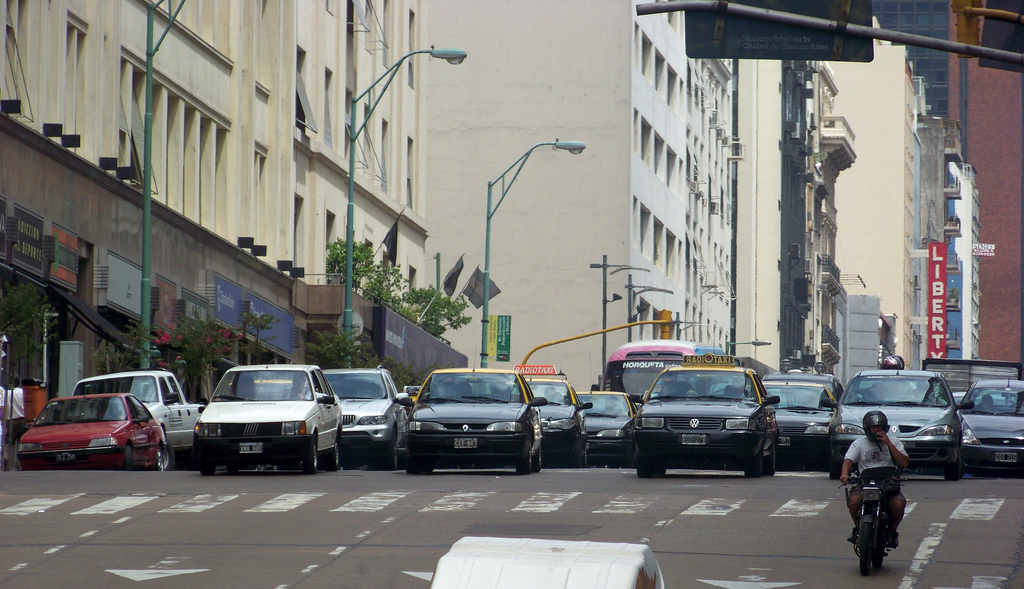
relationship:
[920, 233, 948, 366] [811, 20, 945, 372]
liberty on building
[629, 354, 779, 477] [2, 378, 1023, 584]
car on street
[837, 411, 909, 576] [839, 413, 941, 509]
man on motorbike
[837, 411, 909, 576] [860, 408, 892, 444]
man wears helmet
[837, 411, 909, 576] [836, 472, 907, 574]
man rides motorcycle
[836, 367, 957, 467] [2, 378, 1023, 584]
car on street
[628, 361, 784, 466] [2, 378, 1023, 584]
car on street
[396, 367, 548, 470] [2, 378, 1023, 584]
car on street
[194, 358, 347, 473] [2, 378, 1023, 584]
car on street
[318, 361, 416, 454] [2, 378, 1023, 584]
car on street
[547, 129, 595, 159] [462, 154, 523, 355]
light on pole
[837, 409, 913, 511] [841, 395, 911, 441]
man wearing helmet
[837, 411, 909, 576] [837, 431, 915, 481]
man wearing shirt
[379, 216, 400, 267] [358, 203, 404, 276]
flag on pole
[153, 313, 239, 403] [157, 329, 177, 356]
tree with flowers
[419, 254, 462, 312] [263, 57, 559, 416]
flag on building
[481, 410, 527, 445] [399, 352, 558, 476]
headlight of car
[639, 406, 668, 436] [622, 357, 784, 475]
headlight of car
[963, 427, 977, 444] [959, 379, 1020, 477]
headlight of car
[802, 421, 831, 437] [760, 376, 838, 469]
headlight of car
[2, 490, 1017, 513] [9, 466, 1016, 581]
lines on street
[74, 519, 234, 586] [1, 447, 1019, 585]
arrows on street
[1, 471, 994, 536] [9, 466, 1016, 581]
lines painted on street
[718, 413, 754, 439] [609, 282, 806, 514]
headlight of a car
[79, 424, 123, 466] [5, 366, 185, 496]
headlight of a car